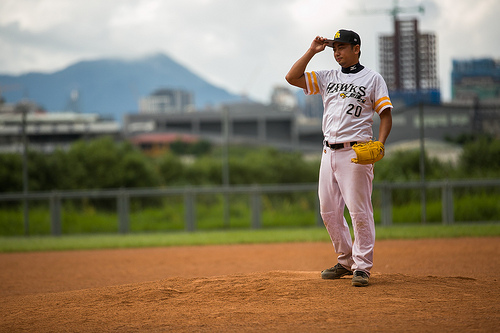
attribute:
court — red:
[1, 234, 499, 332]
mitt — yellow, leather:
[349, 137, 388, 167]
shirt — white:
[301, 61, 395, 144]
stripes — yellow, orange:
[305, 70, 322, 97]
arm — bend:
[282, 31, 331, 102]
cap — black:
[322, 25, 364, 48]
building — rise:
[376, 12, 445, 99]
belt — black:
[319, 138, 358, 151]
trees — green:
[0, 133, 303, 212]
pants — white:
[314, 145, 382, 273]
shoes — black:
[316, 259, 375, 289]